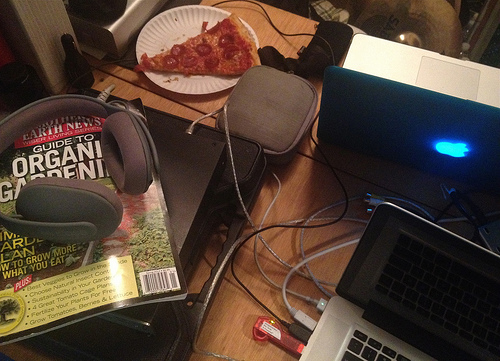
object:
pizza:
[133, 10, 261, 77]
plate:
[134, 4, 261, 98]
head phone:
[0, 92, 160, 244]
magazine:
[1, 95, 189, 344]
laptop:
[292, 200, 500, 361]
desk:
[0, 0, 500, 361]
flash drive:
[250, 316, 307, 356]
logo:
[433, 137, 470, 160]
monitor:
[334, 200, 499, 353]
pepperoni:
[194, 41, 214, 56]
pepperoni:
[221, 47, 234, 60]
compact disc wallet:
[214, 63, 319, 164]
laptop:
[315, 33, 499, 191]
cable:
[230, 183, 332, 293]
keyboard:
[335, 329, 414, 361]